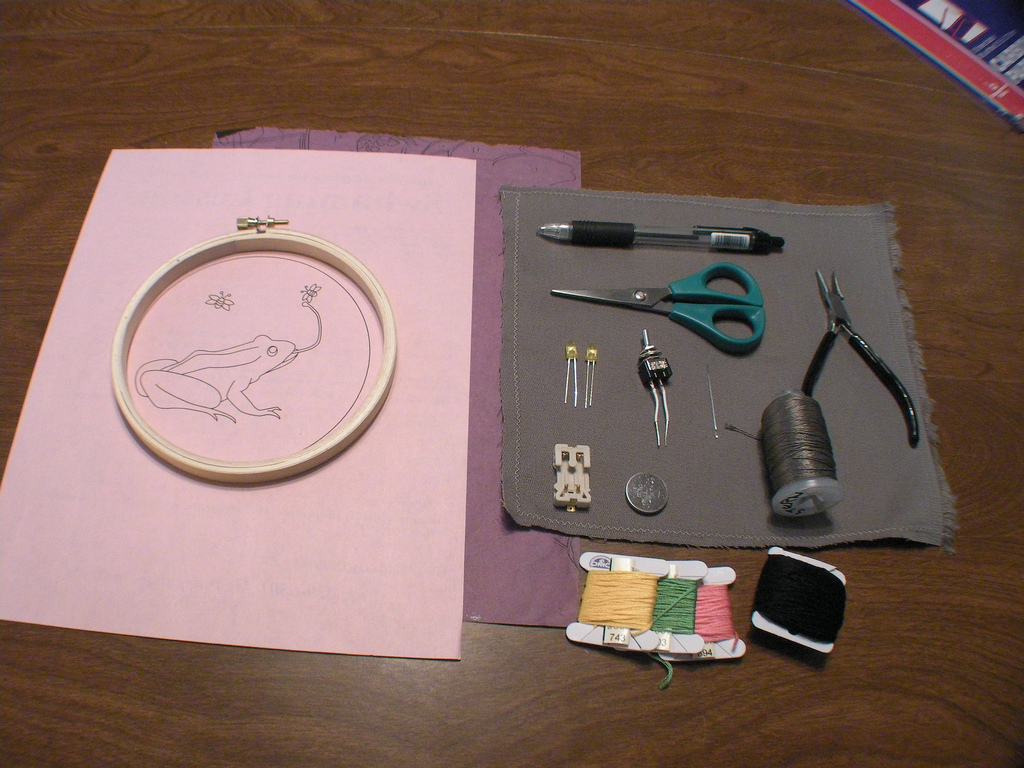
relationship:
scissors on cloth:
[548, 268, 821, 351] [487, 139, 917, 537]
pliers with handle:
[801, 269, 919, 450] [803, 329, 929, 446]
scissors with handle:
[552, 262, 766, 354] [672, 256, 768, 358]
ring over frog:
[110, 232, 400, 481] [138, 327, 309, 423]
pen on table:
[536, 220, 786, 256] [13, 9, 988, 740]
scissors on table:
[552, 262, 766, 354] [13, 9, 988, 740]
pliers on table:
[801, 269, 919, 450] [13, 9, 988, 740]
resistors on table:
[565, 340, 599, 409] [13, 9, 988, 740]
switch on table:
[637, 328, 674, 446] [13, 9, 988, 740]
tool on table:
[552, 443, 591, 512] [13, 9, 988, 740]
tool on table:
[110, 215, 402, 490] [8, 87, 979, 759]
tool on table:
[712, 359, 719, 442] [13, 9, 988, 740]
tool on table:
[725, 388, 845, 518] [13, 9, 988, 740]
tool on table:
[576, 348, 605, 415] [13, 9, 988, 740]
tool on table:
[563, 335, 581, 413] [13, 9, 988, 740]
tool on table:
[555, 439, 597, 502] [13, 9, 988, 740]